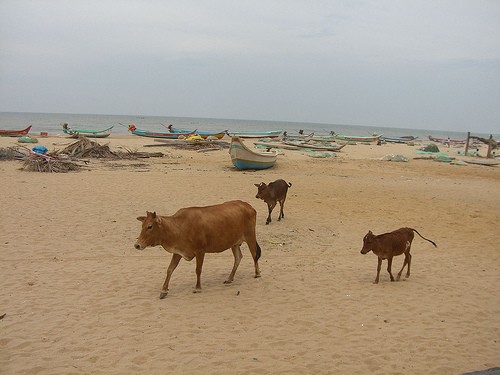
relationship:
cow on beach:
[136, 199, 262, 299] [2, 133, 495, 368]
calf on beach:
[362, 227, 438, 279] [2, 133, 495, 368]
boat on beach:
[228, 133, 286, 169] [2, 133, 495, 368]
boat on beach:
[129, 124, 197, 138] [2, 133, 495, 368]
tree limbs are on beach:
[17, 151, 91, 172] [2, 133, 495, 368]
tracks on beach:
[148, 165, 220, 175] [2, 133, 495, 368]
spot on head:
[259, 183, 262, 186] [255, 181, 268, 199]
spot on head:
[363, 236, 367, 239] [360, 229, 375, 254]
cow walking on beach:
[136, 199, 262, 299] [2, 133, 495, 368]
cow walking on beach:
[254, 178, 292, 224] [2, 133, 495, 368]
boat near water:
[228, 133, 286, 169] [4, 109, 495, 141]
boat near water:
[129, 124, 197, 138] [4, 109, 495, 141]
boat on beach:
[369, 132, 418, 143] [2, 133, 495, 368]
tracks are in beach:
[148, 165, 220, 175] [2, 133, 495, 368]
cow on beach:
[254, 178, 292, 224] [2, 133, 495, 368]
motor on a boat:
[127, 123, 135, 131] [129, 124, 197, 138]